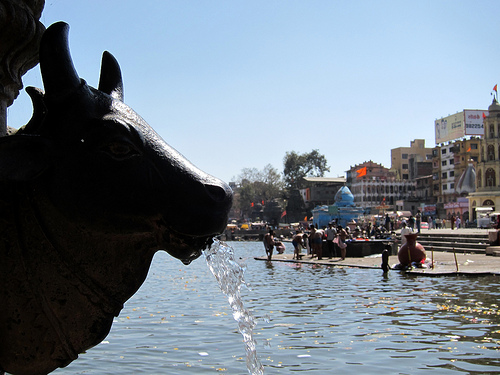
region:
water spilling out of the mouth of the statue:
[201, 237, 259, 372]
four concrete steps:
[392, 230, 487, 252]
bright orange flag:
[355, 162, 365, 174]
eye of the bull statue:
[107, 138, 137, 158]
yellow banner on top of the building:
[435, 110, 462, 140]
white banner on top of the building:
[461, 107, 486, 133]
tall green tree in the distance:
[282, 147, 329, 190]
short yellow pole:
[427, 246, 433, 267]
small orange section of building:
[302, 185, 309, 200]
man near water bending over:
[291, 232, 308, 259]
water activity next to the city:
[51, 8, 493, 315]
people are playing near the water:
[258, 225, 444, 282]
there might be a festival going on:
[257, 188, 472, 283]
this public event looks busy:
[252, 183, 396, 267]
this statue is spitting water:
[35, 38, 285, 361]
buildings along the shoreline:
[265, 133, 489, 218]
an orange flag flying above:
[344, 157, 377, 183]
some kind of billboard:
[425, 104, 487, 145]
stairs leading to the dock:
[414, 218, 491, 256]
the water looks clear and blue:
[153, 251, 496, 356]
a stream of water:
[206, 235, 274, 367]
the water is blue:
[85, 232, 497, 374]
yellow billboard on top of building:
[426, 105, 477, 147]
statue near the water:
[375, 244, 396, 274]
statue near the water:
[291, 229, 306, 260]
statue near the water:
[257, 231, 282, 266]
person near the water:
[333, 223, 348, 259]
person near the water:
[322, 218, 340, 255]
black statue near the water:
[0, 3, 258, 373]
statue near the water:
[392, 227, 429, 273]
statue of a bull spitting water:
[4, 55, 232, 370]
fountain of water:
[200, 230, 278, 372]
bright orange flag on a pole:
[355, 166, 372, 226]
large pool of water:
[229, 258, 469, 361]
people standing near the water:
[259, 220, 355, 265]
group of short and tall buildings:
[336, 94, 496, 233]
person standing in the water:
[378, 245, 394, 276]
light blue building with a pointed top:
[315, 185, 361, 225]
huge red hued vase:
[400, 231, 425, 262]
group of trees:
[235, 148, 334, 233]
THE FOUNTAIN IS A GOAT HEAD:
[3, 25, 255, 374]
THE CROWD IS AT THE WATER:
[246, 213, 443, 283]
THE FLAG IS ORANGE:
[350, 163, 370, 182]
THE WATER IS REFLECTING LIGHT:
[38, 235, 499, 373]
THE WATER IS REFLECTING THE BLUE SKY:
[34, 232, 499, 374]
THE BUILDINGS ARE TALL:
[286, 103, 498, 234]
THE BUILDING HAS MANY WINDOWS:
[435, 142, 460, 194]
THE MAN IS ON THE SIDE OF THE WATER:
[260, 227, 282, 260]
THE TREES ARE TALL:
[218, 140, 327, 245]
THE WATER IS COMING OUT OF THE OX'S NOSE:
[186, 230, 272, 373]